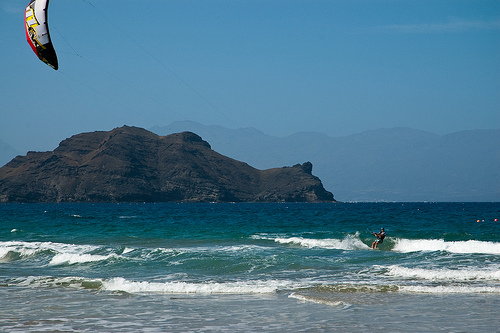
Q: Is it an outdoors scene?
A: Yes, it is outdoors.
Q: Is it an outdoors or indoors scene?
A: It is outdoors.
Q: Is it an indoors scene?
A: No, it is outdoors.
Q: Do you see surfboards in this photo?
A: No, there are no surfboards.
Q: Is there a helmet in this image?
A: No, there are no helmets.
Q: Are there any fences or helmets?
A: No, there are no helmets or fences.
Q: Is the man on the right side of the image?
A: Yes, the man is on the right of the image.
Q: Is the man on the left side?
A: No, the man is on the right of the image.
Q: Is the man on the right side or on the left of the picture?
A: The man is on the right of the image.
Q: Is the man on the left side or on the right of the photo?
A: The man is on the right of the image.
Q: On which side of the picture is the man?
A: The man is on the right of the image.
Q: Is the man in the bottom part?
A: Yes, the man is in the bottom of the image.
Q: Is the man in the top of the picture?
A: No, the man is in the bottom of the image.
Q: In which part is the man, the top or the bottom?
A: The man is in the bottom of the image.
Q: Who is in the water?
A: The man is in the water.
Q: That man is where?
A: The man is in the water.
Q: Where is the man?
A: The man is in the water.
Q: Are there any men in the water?
A: Yes, there is a man in the water.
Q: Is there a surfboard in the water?
A: No, there is a man in the water.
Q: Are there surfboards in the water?
A: No, there is a man in the water.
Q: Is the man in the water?
A: Yes, the man is in the water.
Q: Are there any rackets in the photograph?
A: No, there are no rackets.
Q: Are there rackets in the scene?
A: No, there are no rackets.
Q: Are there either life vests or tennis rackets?
A: No, there are no tennis rackets or life vests.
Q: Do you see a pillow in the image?
A: No, there are no pillows.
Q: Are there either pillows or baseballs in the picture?
A: No, there are no pillows or baseballs.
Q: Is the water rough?
A: Yes, the water is rough.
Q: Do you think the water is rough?
A: Yes, the water is rough.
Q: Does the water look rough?
A: Yes, the water is rough.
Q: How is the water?
A: The water is rough.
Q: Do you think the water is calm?
A: No, the water is rough.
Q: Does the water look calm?
A: No, the water is rough.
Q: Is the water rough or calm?
A: The water is rough.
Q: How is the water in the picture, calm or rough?
A: The water is rough.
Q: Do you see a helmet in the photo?
A: No, there are no helmets.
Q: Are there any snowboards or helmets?
A: No, there are no helmets or snowboards.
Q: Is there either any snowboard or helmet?
A: No, there are no helmets or snowboards.